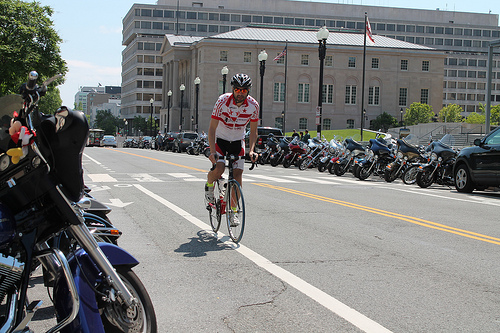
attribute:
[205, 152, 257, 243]
bicycle — white , red 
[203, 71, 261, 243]
man — pink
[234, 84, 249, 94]
glasses — amber, riding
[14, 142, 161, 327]
motorcycle — blue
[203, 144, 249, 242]
bicycle — multi-speed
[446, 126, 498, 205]
car — black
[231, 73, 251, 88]
helmet — black , white 